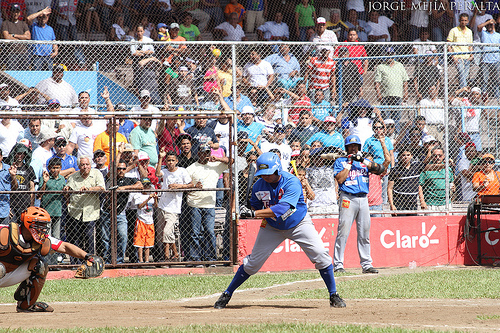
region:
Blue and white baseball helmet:
[239, 147, 293, 189]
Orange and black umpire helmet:
[12, 200, 64, 250]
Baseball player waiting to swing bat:
[194, 118, 358, 320]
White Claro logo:
[376, 213, 451, 261]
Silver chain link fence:
[4, 33, 499, 275]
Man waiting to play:
[312, 129, 387, 274]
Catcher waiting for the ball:
[2, 203, 116, 314]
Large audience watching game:
[0, 4, 497, 266]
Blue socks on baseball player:
[209, 256, 257, 293]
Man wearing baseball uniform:
[179, 143, 361, 313]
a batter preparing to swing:
[211, 149, 346, 309]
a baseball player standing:
[328, 133, 386, 274]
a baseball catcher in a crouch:
[0, 204, 105, 314]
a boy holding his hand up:
[153, 144, 195, 264]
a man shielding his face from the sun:
[25, 5, 60, 67]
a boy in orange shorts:
[126, 176, 159, 267]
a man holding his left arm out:
[386, 147, 452, 213]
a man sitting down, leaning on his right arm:
[365, 6, 396, 51]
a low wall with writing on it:
[235, 211, 499, 269]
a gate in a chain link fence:
[112, 111, 233, 267]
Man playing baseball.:
[218, 141, 346, 306]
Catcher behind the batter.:
[1, 203, 109, 313]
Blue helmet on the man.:
[250, 150, 287, 190]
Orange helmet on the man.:
[19, 205, 53, 236]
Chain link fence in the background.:
[0, 35, 498, 267]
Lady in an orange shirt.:
[468, 153, 498, 193]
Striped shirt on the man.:
[304, 45, 336, 97]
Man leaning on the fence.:
[67, 153, 107, 257]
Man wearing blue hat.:
[2, 3, 33, 65]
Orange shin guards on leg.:
[20, 256, 50, 313]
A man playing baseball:
[212, 145, 349, 311]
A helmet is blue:
[249, 146, 285, 179]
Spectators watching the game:
[1, 1, 498, 265]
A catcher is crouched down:
[0, 202, 107, 317]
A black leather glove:
[75, 250, 107, 284]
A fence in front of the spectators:
[1, 35, 497, 268]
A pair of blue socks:
[222, 262, 341, 298]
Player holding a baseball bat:
[212, 147, 351, 312]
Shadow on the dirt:
[178, 296, 319, 314]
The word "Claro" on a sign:
[377, 227, 434, 253]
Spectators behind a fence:
[1, 0, 499, 267]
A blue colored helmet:
[250, 149, 285, 180]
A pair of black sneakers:
[210, 287, 350, 313]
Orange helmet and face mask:
[19, 202, 54, 249]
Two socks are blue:
[222, 260, 340, 300]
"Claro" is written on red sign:
[375, 220, 442, 253]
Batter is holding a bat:
[210, 151, 352, 314]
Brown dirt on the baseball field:
[1, 266, 498, 331]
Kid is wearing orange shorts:
[130, 175, 161, 265]